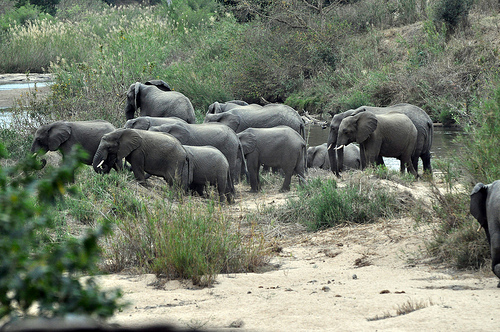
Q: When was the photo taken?
A: Daytime.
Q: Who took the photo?
A: A photographer.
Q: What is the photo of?
A: Elephants.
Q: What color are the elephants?
A: Grey.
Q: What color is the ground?
A: Brown.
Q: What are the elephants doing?
A: Walking.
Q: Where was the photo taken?
A: At an elephant preserve.